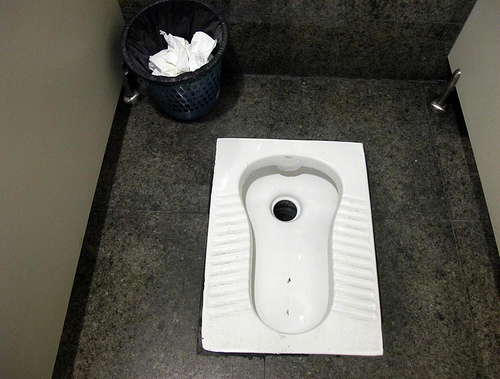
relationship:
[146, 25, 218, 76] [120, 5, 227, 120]
paper in waste basket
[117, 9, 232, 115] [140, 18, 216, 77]
waste basket with trash